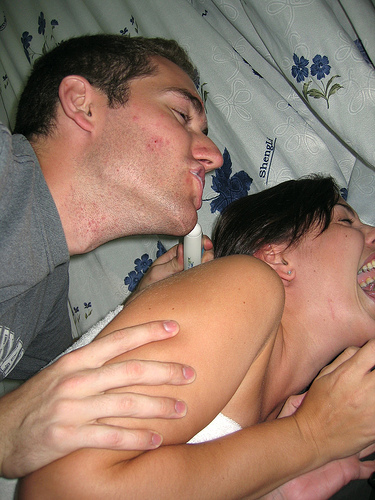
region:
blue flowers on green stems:
[290, 48, 343, 114]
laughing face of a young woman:
[324, 182, 373, 327]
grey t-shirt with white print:
[0, 125, 77, 377]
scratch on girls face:
[324, 286, 341, 325]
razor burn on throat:
[69, 197, 112, 247]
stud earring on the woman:
[285, 266, 296, 279]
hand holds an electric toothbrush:
[144, 217, 210, 273]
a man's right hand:
[3, 303, 197, 464]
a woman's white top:
[174, 398, 244, 449]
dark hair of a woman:
[211, 172, 341, 259]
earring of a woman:
[286, 268, 291, 273]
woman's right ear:
[251, 238, 298, 282]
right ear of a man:
[57, 73, 99, 138]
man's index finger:
[70, 314, 181, 358]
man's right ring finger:
[77, 389, 187, 422]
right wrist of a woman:
[282, 406, 327, 480]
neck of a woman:
[283, 324, 315, 400]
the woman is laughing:
[259, 177, 372, 344]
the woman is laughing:
[268, 171, 371, 322]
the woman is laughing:
[246, 166, 372, 349]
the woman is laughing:
[301, 182, 372, 301]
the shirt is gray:
[0, 113, 93, 400]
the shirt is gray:
[4, 113, 79, 398]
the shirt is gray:
[0, 106, 75, 406]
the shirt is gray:
[4, 122, 100, 386]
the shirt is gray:
[2, 118, 100, 437]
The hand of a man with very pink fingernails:
[0, 318, 196, 479]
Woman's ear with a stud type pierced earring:
[258, 240, 296, 282]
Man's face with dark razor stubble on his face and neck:
[56, 56, 224, 256]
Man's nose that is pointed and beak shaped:
[189, 129, 225, 171]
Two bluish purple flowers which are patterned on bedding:
[290, 51, 344, 109]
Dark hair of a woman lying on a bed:
[211, 171, 342, 259]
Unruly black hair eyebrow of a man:
[161, 85, 203, 116]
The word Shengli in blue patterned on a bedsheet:
[255, 134, 277, 186]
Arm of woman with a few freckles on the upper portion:
[12, 252, 286, 498]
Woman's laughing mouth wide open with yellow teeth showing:
[355, 255, 373, 303]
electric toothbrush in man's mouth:
[181, 219, 202, 270]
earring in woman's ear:
[287, 270, 291, 273]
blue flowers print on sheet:
[288, 51, 343, 109]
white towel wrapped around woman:
[0, 301, 243, 498]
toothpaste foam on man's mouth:
[191, 170, 202, 186]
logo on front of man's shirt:
[0, 324, 25, 378]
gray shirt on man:
[0, 123, 73, 380]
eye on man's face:
[172, 105, 191, 124]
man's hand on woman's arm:
[1, 318, 196, 479]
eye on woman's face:
[336, 215, 351, 223]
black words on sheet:
[243, 129, 278, 172]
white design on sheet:
[219, 81, 251, 108]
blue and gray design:
[286, 50, 351, 111]